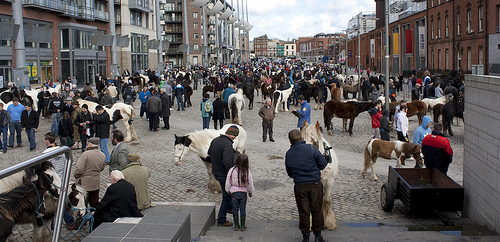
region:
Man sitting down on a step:
[92, 169, 141, 224]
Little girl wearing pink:
[224, 154, 256, 227]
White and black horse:
[172, 123, 246, 189]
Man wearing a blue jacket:
[282, 128, 330, 240]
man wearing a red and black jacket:
[420, 121, 455, 173]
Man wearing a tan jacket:
[256, 98, 276, 142]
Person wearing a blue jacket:
[199, 92, 211, 129]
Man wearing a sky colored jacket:
[286, 94, 312, 126]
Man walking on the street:
[18, 103, 40, 148]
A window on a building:
[455, 7, 464, 39]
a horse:
[157, 135, 212, 170]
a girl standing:
[222, 155, 261, 227]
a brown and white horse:
[360, 133, 422, 164]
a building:
[180, 2, 205, 51]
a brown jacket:
[80, 153, 108, 178]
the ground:
[147, 132, 166, 165]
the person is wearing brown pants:
[296, 185, 322, 229]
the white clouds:
[276, 13, 335, 30]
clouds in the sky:
[264, 13, 321, 33]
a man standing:
[255, 96, 286, 142]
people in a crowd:
[136, 50, 351, 91]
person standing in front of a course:
[267, 120, 348, 231]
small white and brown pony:
[363, 123, 419, 178]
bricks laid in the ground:
[0, 65, 457, 221]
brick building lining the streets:
[251, 0, 496, 70]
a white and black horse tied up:
[0, 145, 96, 235]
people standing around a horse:
[40, 88, 138, 134]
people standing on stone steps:
[93, 197, 488, 237]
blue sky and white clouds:
[248, 1, 359, 36]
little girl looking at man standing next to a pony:
[219, 150, 264, 227]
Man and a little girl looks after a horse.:
[171, 126, 276, 231]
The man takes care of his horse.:
[282, 119, 354, 239]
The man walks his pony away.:
[362, 113, 434, 171]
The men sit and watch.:
[97, 150, 154, 219]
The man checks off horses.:
[291, 92, 316, 128]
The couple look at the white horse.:
[201, 93, 229, 128]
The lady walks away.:
[76, 103, 93, 148]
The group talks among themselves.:
[145, 89, 179, 131]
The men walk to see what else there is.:
[0, 98, 40, 151]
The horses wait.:
[1, 155, 91, 239]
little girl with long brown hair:
[223, 154, 254, 229]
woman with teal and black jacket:
[197, 88, 216, 128]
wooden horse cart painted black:
[373, 158, 467, 222]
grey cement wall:
[462, 65, 499, 237]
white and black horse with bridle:
[173, 120, 253, 192]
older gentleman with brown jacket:
[254, 90, 276, 148]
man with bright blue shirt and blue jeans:
[7, 96, 24, 145]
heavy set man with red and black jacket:
[417, 120, 455, 169]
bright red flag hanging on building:
[402, 24, 414, 59]